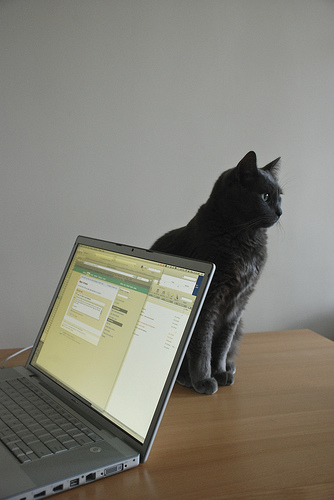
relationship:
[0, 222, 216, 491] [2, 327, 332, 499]
laptop open on table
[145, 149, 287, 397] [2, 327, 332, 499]
cat sitting on table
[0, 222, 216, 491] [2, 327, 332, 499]
laptop was left open on table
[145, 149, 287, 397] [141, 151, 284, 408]
cat color grey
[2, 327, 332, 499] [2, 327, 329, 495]
table color brown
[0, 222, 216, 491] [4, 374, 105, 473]
laptop on table gray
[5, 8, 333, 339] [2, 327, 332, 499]
wall seen behind table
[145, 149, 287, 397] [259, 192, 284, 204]
cats eyes are black and white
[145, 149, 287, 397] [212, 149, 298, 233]
cat looks at one direction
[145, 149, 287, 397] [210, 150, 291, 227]
cat has a head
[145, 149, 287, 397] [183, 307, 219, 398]
cat has a leg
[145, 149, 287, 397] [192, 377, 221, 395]
cat has paw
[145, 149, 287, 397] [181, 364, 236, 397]
cat has four paws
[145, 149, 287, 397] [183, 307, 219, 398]
cat sits on h leg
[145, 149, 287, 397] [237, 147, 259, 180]
cat has an ear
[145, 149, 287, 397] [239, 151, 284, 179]
cat has two ears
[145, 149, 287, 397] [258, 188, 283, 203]
cat has eyes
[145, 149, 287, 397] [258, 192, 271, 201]
cat looks out of an eye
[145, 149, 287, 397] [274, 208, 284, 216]
cat has a nose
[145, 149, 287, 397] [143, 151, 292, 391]
cat has fur thats black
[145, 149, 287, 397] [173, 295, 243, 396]
cat has legs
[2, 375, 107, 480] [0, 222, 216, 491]
keyboard th on laptop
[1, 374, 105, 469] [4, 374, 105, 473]
keyboard color gray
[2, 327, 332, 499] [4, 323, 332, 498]
tabletop made of wood